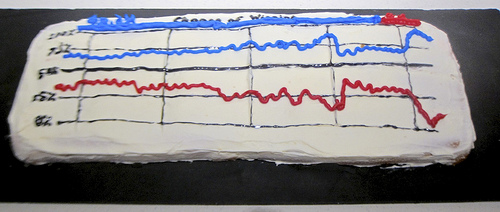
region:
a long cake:
[10, 12, 497, 194]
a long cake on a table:
[16, 20, 482, 209]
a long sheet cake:
[15, 21, 499, 155]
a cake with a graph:
[23, 20, 497, 195]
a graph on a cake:
[29, 10, 449, 191]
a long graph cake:
[29, 21, 490, 208]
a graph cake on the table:
[32, 30, 491, 210]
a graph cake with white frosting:
[28, 32, 499, 201]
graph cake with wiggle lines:
[40, 21, 449, 163]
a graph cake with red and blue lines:
[23, 10, 494, 191]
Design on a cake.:
[40, 19, 461, 169]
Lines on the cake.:
[83, 33, 432, 133]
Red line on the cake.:
[49, 65, 299, 133]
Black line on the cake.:
[70, 49, 327, 98]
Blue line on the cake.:
[67, 32, 280, 72]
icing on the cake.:
[131, 92, 417, 209]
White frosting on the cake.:
[164, 99, 468, 195]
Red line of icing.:
[233, 57, 344, 117]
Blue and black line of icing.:
[185, 26, 267, 98]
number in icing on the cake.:
[42, 34, 77, 62]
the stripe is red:
[50, 74, 440, 133]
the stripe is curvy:
[47, 75, 443, 125]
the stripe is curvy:
[60, 30, 417, 67]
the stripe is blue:
[55, 29, 435, 59]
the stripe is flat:
[75, 13, 384, 27]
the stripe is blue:
[76, 10, 394, 29]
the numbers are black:
[28, 25, 67, 127]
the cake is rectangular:
[5, 0, 473, 190]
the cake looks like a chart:
[43, 4, 442, 124]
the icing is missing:
[438, 135, 468, 157]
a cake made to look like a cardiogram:
[6, 18, 488, 174]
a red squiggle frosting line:
[49, 74, 454, 129]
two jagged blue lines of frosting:
[57, 16, 445, 70]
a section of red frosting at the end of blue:
[376, 10, 426, 32]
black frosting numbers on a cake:
[35, 29, 72, 129]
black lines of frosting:
[65, 96, 135, 125]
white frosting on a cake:
[49, 128, 170, 160]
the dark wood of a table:
[171, 161, 298, 198]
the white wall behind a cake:
[441, 0, 468, 8]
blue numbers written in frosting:
[79, 12, 146, 29]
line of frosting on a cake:
[51, 76, 448, 131]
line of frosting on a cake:
[58, 25, 441, 65]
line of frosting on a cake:
[65, 13, 428, 31]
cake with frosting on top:
[12, 14, 488, 192]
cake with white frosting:
[4, 1, 474, 203]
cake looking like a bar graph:
[5, 6, 482, 196]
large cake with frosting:
[5, 4, 486, 202]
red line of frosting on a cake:
[45, 67, 457, 147]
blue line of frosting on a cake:
[51, 26, 443, 77]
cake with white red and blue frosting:
[0, 1, 477, 187]